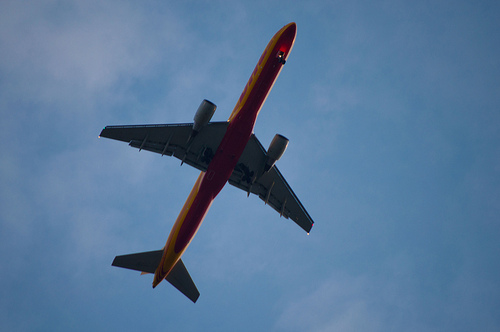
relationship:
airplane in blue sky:
[98, 21, 316, 303] [1, 0, 500, 332]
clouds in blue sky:
[0, 3, 425, 329] [1, 0, 500, 332]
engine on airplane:
[189, 97, 216, 137] [98, 21, 316, 303]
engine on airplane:
[265, 127, 288, 175] [98, 21, 316, 303]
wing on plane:
[82, 121, 232, 176] [144, 79, 291, 217]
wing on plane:
[227, 129, 315, 238] [144, 79, 291, 217]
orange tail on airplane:
[138, 195, 198, 302] [98, 21, 316, 303]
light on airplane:
[255, 18, 284, 67] [98, 21, 316, 303]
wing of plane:
[82, 121, 232, 176] [90, 17, 349, 306]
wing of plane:
[227, 129, 315, 238] [90, 17, 349, 306]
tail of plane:
[110, 246, 200, 303] [86, 9, 332, 304]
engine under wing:
[265, 127, 288, 175] [227, 129, 315, 238]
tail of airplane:
[110, 246, 200, 303] [98, 21, 316, 303]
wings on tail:
[112, 247, 167, 275] [110, 246, 200, 303]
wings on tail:
[162, 258, 201, 302] [110, 246, 200, 303]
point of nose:
[289, 19, 298, 29] [285, 19, 302, 31]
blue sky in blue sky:
[1, 0, 500, 332] [1, 0, 500, 332]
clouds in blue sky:
[0, 3, 458, 332] [1, 1, 498, 328]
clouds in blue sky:
[0, 3, 458, 332] [1, 0, 500, 332]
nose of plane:
[273, 13, 313, 50] [70, 16, 360, 313]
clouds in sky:
[0, 3, 458, 332] [41, 225, 113, 329]